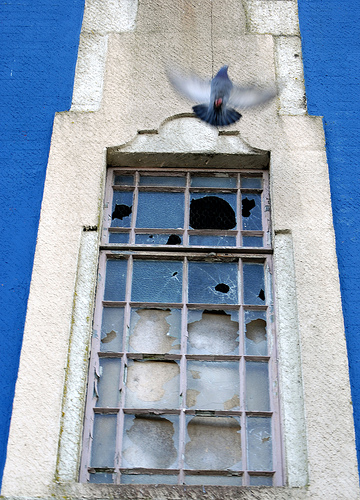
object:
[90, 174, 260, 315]
window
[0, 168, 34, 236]
blue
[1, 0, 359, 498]
building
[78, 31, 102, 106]
white section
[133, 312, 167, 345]
stone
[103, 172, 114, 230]
wooden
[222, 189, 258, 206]
trim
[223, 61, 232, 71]
beak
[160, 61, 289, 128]
bird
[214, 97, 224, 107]
feet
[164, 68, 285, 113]
flight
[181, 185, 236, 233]
broken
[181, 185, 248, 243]
pane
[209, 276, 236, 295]
rock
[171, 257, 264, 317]
in glass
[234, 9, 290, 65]
wall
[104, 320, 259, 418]
boad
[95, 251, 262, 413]
broken window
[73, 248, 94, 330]
white framing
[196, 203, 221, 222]
dark room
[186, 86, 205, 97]
white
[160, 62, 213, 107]
wing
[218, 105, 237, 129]
feathers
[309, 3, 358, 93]
air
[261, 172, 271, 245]
paint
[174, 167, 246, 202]
frame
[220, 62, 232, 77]
head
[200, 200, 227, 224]
hole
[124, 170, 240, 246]
panes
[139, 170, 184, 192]
glass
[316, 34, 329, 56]
sky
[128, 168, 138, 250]
lines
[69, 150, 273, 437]
windows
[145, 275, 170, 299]
thin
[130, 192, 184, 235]
frosted glass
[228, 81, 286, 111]
wings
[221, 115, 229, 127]
black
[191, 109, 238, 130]
tail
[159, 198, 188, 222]
patch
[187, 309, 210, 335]
jagged